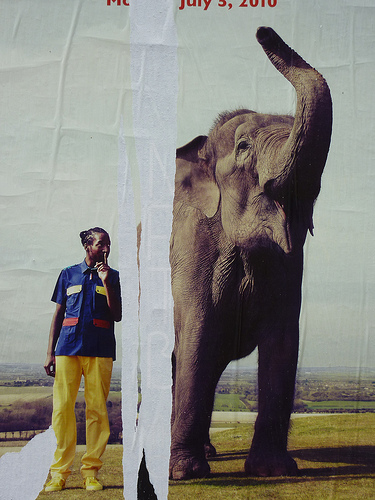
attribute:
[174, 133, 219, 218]
ear — grey, large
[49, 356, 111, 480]
pants — yellow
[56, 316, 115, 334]
flaps — red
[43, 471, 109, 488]
shoes — yellow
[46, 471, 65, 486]
lace — yellow, shoe 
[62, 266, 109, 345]
shirt — blue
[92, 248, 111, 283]
fingers — guy's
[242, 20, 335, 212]
trunk — elephant, grey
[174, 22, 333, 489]
elephant — standing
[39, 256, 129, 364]
shirt — blue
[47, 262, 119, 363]
blue shirt — with four pockets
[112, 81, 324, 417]
elephant — large, grey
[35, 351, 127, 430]
pants — yellow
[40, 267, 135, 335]
shirt — blue, short sleeve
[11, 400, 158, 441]
tree — bare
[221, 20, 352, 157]
trunk — raised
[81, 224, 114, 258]
hair — braided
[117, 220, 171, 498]
middle — damaged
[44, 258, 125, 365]
shirt — blue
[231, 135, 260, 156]
eye — dark